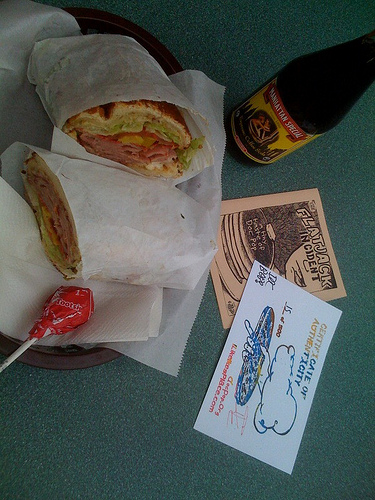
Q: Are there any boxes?
A: No, there are no boxes.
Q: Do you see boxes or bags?
A: No, there are no boxes or bags.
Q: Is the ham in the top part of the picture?
A: Yes, the ham is in the top of the image.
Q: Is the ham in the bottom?
A: No, the ham is in the top of the image.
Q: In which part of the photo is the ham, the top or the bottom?
A: The ham is in the top of the image.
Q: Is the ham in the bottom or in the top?
A: The ham is in the top of the image.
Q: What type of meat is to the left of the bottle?
A: The meat is ham.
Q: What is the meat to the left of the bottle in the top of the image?
A: The meat is ham.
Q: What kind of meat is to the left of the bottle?
A: The meat is ham.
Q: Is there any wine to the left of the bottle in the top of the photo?
A: No, there is ham to the left of the bottle.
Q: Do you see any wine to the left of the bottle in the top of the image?
A: No, there is ham to the left of the bottle.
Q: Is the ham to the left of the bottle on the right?
A: Yes, the ham is to the left of the bottle.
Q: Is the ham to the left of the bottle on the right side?
A: Yes, the ham is to the left of the bottle.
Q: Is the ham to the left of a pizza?
A: No, the ham is to the left of the bottle.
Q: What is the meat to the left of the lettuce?
A: The meat is ham.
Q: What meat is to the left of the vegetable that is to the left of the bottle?
A: The meat is ham.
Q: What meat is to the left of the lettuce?
A: The meat is ham.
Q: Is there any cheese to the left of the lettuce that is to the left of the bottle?
A: No, there is ham to the left of the lettuce.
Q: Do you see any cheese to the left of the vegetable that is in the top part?
A: No, there is ham to the left of the lettuce.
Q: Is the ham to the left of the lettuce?
A: Yes, the ham is to the left of the lettuce.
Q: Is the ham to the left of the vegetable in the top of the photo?
A: Yes, the ham is to the left of the lettuce.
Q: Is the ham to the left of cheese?
A: No, the ham is to the left of the lettuce.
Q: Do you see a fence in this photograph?
A: No, there are no fences.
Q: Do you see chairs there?
A: No, there are no chairs.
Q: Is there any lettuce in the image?
A: Yes, there is lettuce.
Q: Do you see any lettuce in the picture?
A: Yes, there is lettuce.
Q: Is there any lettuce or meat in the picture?
A: Yes, there is lettuce.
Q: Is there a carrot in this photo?
A: No, there are no carrots.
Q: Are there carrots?
A: No, there are no carrots.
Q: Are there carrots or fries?
A: No, there are no carrots or fries.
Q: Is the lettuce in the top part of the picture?
A: Yes, the lettuce is in the top of the image.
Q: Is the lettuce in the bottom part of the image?
A: No, the lettuce is in the top of the image.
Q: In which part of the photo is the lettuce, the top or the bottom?
A: The lettuce is in the top of the image.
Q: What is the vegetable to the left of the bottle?
A: The vegetable is lettuce.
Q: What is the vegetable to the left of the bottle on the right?
A: The vegetable is lettuce.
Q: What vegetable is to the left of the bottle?
A: The vegetable is lettuce.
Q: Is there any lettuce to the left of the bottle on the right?
A: Yes, there is lettuce to the left of the bottle.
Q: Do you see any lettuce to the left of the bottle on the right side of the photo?
A: Yes, there is lettuce to the left of the bottle.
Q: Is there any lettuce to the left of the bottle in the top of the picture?
A: Yes, there is lettuce to the left of the bottle.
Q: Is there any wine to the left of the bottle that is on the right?
A: No, there is lettuce to the left of the bottle.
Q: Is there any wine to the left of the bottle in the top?
A: No, there is lettuce to the left of the bottle.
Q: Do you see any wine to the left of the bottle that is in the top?
A: No, there is lettuce to the left of the bottle.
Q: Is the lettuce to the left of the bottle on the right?
A: Yes, the lettuce is to the left of the bottle.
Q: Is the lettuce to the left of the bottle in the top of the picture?
A: Yes, the lettuce is to the left of the bottle.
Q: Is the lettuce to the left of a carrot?
A: No, the lettuce is to the left of the bottle.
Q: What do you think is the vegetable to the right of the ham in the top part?
A: The vegetable is lettuce.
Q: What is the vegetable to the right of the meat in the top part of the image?
A: The vegetable is lettuce.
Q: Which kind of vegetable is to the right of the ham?
A: The vegetable is lettuce.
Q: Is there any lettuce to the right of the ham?
A: Yes, there is lettuce to the right of the ham.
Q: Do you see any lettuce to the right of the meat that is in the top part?
A: Yes, there is lettuce to the right of the ham.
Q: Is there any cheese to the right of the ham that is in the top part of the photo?
A: No, there is lettuce to the right of the ham.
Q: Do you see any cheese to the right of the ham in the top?
A: No, there is lettuce to the right of the ham.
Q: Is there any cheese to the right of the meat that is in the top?
A: No, there is lettuce to the right of the ham.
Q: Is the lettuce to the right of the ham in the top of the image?
A: Yes, the lettuce is to the right of the ham.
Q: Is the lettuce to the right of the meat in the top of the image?
A: Yes, the lettuce is to the right of the ham.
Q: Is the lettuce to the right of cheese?
A: No, the lettuce is to the right of the ham.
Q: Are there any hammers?
A: No, there are no hammers.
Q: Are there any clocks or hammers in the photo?
A: No, there are no hammers or clocks.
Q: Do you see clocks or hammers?
A: No, there are no hammers or clocks.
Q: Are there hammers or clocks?
A: No, there are no hammers or clocks.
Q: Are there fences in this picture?
A: No, there are no fences.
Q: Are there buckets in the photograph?
A: No, there are no buckets.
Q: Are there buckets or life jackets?
A: No, there are no buckets or life jackets.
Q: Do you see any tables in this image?
A: Yes, there is a table.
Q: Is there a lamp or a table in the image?
A: Yes, there is a table.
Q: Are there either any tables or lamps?
A: Yes, there is a table.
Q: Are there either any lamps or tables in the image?
A: Yes, there is a table.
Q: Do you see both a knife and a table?
A: No, there is a table but no knives.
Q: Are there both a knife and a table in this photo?
A: No, there is a table but no knives.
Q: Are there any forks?
A: No, there are no forks.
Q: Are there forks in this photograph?
A: No, there are no forks.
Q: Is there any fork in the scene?
A: No, there are no forks.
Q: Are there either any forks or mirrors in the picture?
A: No, there are no forks or mirrors.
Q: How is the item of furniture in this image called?
A: The piece of furniture is a table.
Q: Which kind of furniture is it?
A: The piece of furniture is a table.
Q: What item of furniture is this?
A: This is a table.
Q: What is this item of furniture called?
A: This is a table.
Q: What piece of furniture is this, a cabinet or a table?
A: This is a table.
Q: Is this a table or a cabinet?
A: This is a table.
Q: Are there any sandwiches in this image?
A: Yes, there is a sandwich.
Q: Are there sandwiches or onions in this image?
A: Yes, there is a sandwich.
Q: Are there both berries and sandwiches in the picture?
A: No, there is a sandwich but no berries.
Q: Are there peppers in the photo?
A: No, there are no peppers.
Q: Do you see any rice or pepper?
A: No, there are no peppers or rice.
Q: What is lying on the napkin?
A: The sandwich is lying on the napkin.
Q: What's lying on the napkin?
A: The sandwich is lying on the napkin.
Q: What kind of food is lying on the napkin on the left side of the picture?
A: The food is a sandwich.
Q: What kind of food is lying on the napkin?
A: The food is a sandwich.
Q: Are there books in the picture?
A: No, there are no books.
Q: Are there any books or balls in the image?
A: No, there are no books or balls.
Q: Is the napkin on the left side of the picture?
A: Yes, the napkin is on the left of the image.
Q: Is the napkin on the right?
A: No, the napkin is on the left of the image.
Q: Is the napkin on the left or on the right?
A: The napkin is on the left of the image.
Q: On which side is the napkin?
A: The napkin is on the left of the image.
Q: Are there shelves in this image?
A: No, there are no shelves.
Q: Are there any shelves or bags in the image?
A: No, there are no shelves or bags.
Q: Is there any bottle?
A: Yes, there is a bottle.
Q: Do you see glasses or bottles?
A: Yes, there is a bottle.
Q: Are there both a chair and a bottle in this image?
A: No, there is a bottle but no chairs.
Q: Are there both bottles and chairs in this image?
A: No, there is a bottle but no chairs.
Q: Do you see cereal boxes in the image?
A: No, there are no cereal boxes.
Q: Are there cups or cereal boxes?
A: No, there are no cereal boxes or cups.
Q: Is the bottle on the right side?
A: Yes, the bottle is on the right of the image.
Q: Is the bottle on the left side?
A: No, the bottle is on the right of the image.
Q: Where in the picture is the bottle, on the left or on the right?
A: The bottle is on the right of the image.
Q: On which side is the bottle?
A: The bottle is on the right of the image.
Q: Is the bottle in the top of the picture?
A: Yes, the bottle is in the top of the image.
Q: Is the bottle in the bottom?
A: No, the bottle is in the top of the image.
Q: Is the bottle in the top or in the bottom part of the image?
A: The bottle is in the top of the image.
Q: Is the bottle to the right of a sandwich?
A: Yes, the bottle is to the right of a sandwich.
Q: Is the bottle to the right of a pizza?
A: No, the bottle is to the right of a sandwich.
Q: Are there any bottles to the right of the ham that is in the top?
A: Yes, there is a bottle to the right of the ham.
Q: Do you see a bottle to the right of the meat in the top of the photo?
A: Yes, there is a bottle to the right of the ham.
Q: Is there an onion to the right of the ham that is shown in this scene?
A: No, there is a bottle to the right of the ham.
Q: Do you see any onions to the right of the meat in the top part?
A: No, there is a bottle to the right of the ham.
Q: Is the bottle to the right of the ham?
A: Yes, the bottle is to the right of the ham.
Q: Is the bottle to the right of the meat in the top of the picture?
A: Yes, the bottle is to the right of the ham.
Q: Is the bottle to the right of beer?
A: No, the bottle is to the right of the ham.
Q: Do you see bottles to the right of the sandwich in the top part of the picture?
A: Yes, there is a bottle to the right of the sandwich.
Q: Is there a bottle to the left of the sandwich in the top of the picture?
A: No, the bottle is to the right of the sandwich.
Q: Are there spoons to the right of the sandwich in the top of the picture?
A: No, there is a bottle to the right of the sandwich.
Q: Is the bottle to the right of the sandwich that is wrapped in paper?
A: Yes, the bottle is to the right of the sandwich.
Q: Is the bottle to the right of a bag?
A: No, the bottle is to the right of the sandwich.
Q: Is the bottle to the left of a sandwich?
A: No, the bottle is to the right of a sandwich.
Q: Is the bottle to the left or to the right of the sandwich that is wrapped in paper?
A: The bottle is to the right of the sandwich.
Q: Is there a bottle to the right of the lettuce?
A: Yes, there is a bottle to the right of the lettuce.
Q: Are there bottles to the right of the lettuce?
A: Yes, there is a bottle to the right of the lettuce.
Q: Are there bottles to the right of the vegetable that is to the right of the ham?
A: Yes, there is a bottle to the right of the lettuce.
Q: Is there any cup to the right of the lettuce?
A: No, there is a bottle to the right of the lettuce.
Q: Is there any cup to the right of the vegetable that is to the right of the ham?
A: No, there is a bottle to the right of the lettuce.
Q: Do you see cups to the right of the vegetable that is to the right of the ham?
A: No, there is a bottle to the right of the lettuce.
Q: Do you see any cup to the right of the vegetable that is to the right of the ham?
A: No, there is a bottle to the right of the lettuce.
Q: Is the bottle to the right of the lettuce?
A: Yes, the bottle is to the right of the lettuce.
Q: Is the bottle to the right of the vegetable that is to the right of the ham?
A: Yes, the bottle is to the right of the lettuce.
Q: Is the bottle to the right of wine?
A: No, the bottle is to the right of the lettuce.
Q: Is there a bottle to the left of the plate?
A: No, the bottle is to the right of the plate.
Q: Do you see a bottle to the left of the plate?
A: No, the bottle is to the right of the plate.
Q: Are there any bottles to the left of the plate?
A: No, the bottle is to the right of the plate.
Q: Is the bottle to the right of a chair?
A: No, the bottle is to the right of the plate.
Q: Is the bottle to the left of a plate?
A: No, the bottle is to the right of a plate.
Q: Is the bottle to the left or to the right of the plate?
A: The bottle is to the right of the plate.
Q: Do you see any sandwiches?
A: Yes, there is a sandwich.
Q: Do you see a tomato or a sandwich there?
A: Yes, there is a sandwich.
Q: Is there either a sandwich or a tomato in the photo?
A: Yes, there is a sandwich.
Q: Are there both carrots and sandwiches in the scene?
A: No, there is a sandwich but no carrots.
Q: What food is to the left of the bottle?
A: The food is a sandwich.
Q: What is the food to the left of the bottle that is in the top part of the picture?
A: The food is a sandwich.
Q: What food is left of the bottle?
A: The food is a sandwich.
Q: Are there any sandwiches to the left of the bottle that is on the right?
A: Yes, there is a sandwich to the left of the bottle.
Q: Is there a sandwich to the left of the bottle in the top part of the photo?
A: Yes, there is a sandwich to the left of the bottle.